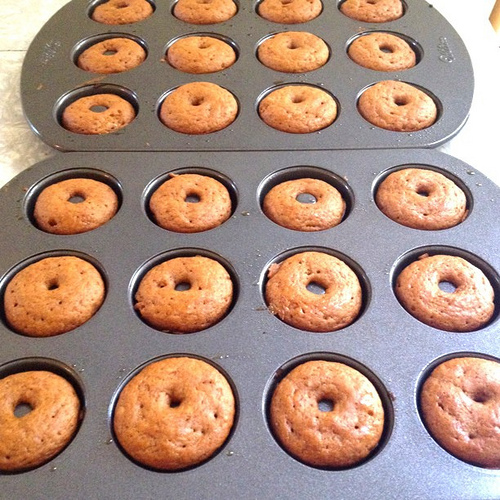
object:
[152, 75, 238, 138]
doughnut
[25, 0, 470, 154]
pan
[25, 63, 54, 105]
crumb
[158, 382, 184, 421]
chocolate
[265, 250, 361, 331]
cookie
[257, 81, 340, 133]
doughnut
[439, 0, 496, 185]
table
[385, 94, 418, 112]
hole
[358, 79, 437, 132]
goods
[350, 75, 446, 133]
slot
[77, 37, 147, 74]
items